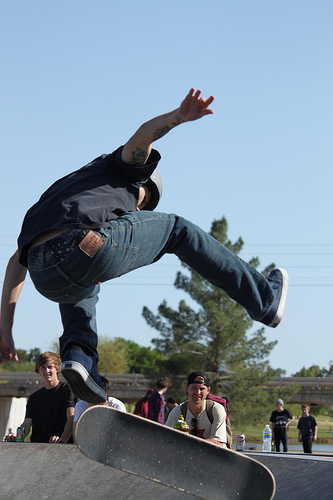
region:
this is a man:
[36, 114, 272, 326]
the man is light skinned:
[133, 132, 143, 142]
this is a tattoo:
[130, 149, 145, 162]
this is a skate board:
[74, 409, 246, 483]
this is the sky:
[220, 88, 320, 209]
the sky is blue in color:
[252, 137, 302, 176]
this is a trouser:
[127, 216, 166, 243]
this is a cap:
[192, 368, 208, 380]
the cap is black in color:
[184, 375, 192, 382]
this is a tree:
[185, 280, 239, 359]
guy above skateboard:
[1, 85, 287, 399]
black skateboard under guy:
[73, 404, 276, 498]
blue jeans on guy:
[20, 209, 276, 360]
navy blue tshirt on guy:
[13, 145, 159, 261]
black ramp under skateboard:
[0, 437, 330, 498]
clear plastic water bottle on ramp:
[261, 422, 272, 450]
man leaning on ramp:
[163, 370, 229, 448]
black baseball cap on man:
[183, 370, 212, 387]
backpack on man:
[180, 392, 229, 428]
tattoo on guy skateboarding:
[151, 124, 172, 142]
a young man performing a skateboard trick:
[33, 97, 300, 498]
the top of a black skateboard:
[80, 399, 277, 498]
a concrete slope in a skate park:
[2, 440, 92, 491]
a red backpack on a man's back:
[208, 389, 229, 418]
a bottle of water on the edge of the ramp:
[256, 422, 274, 453]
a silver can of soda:
[235, 432, 246, 452]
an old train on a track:
[125, 369, 331, 401]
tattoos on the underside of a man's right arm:
[125, 122, 183, 165]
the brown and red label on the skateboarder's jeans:
[76, 229, 105, 257]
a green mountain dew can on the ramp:
[13, 424, 25, 441]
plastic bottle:
[259, 415, 278, 463]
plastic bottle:
[251, 410, 276, 452]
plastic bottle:
[253, 422, 281, 474]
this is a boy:
[0, 92, 236, 331]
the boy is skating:
[0, 80, 280, 343]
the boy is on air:
[3, 120, 258, 359]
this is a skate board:
[142, 440, 217, 479]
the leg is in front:
[217, 239, 292, 337]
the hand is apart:
[172, 87, 215, 126]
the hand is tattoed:
[154, 116, 183, 137]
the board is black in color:
[158, 441, 192, 475]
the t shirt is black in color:
[68, 166, 120, 223]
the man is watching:
[173, 373, 227, 434]